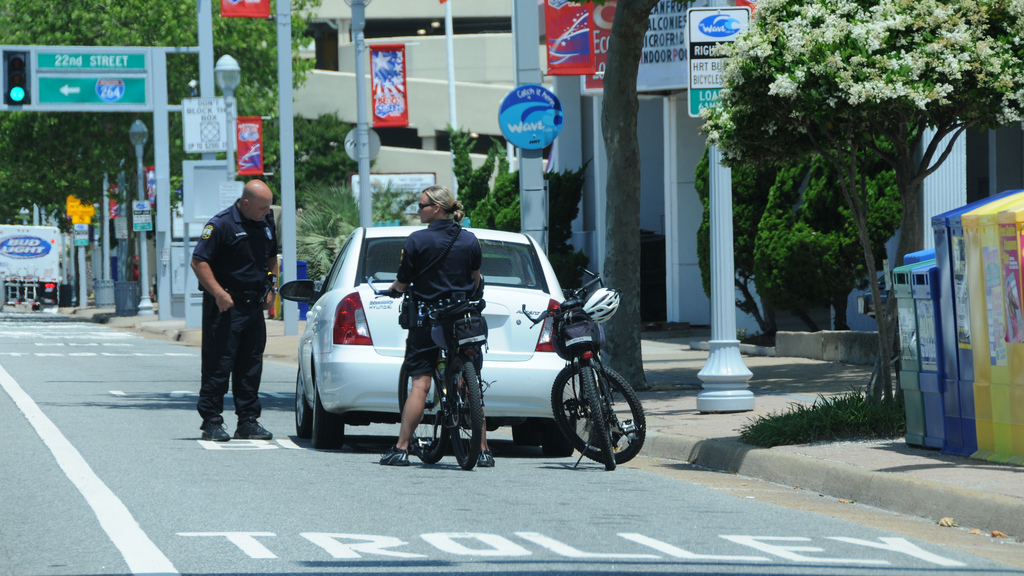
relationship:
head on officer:
[416, 185, 459, 225] [384, 191, 489, 463]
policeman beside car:
[190, 176, 283, 439] [278, 221, 577, 453]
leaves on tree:
[728, 81, 876, 177] [694, 139, 897, 335]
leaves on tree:
[743, 27, 912, 159] [694, 139, 897, 335]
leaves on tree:
[717, 100, 899, 202] [695, 122, 910, 329]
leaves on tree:
[747, 119, 916, 294] [694, 96, 914, 334]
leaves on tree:
[722, 14, 857, 248] [698, 0, 1022, 393]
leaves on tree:
[756, 13, 901, 201] [698, 0, 1022, 393]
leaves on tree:
[753, 152, 903, 315] [698, 0, 1022, 393]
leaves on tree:
[797, 9, 873, 254] [269, 113, 361, 251]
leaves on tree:
[786, 1, 987, 99] [3, 0, 304, 232]